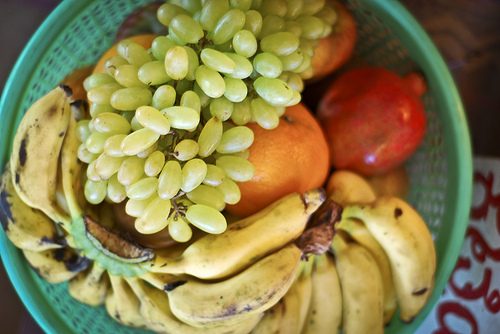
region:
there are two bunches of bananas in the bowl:
[20, 88, 452, 332]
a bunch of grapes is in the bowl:
[74, 5, 344, 237]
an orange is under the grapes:
[222, 98, 329, 214]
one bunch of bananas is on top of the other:
[13, 86, 415, 332]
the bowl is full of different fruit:
[0, 2, 472, 329]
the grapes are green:
[75, 2, 337, 232]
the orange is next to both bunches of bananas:
[235, 104, 331, 210]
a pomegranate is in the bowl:
[315, 63, 422, 167]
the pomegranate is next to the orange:
[231, 66, 427, 215]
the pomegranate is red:
[326, 56, 431, 168]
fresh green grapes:
[73, 0, 340, 255]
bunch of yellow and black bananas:
[3, 78, 453, 332]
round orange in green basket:
[217, 97, 337, 223]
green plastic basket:
[6, 0, 489, 328]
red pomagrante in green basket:
[317, 56, 428, 171]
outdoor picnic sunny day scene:
[10, 1, 496, 326]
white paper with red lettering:
[417, 155, 497, 326]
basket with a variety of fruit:
[5, 0, 490, 326]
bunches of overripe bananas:
[7, 77, 468, 329]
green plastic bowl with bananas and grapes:
[6, 1, 498, 328]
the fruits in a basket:
[24, 52, 411, 332]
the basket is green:
[19, 13, 481, 321]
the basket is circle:
[10, 14, 490, 314]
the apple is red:
[325, 62, 447, 212]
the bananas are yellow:
[185, 233, 458, 328]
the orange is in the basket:
[181, 69, 491, 305]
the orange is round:
[242, 80, 359, 247]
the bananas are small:
[119, 212, 293, 329]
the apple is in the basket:
[311, 35, 498, 282]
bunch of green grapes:
[104, 30, 267, 185]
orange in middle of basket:
[238, 91, 336, 214]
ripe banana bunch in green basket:
[243, 201, 430, 320]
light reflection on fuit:
[362, 114, 411, 166]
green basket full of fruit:
[7, 6, 467, 319]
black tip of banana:
[54, 75, 84, 102]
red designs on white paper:
[459, 193, 496, 314]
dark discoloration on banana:
[387, 199, 407, 224]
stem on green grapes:
[167, 195, 184, 220]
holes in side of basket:
[54, 17, 103, 69]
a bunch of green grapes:
[112, 76, 217, 223]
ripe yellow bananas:
[157, 241, 384, 321]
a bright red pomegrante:
[318, 51, 420, 174]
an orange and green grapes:
[220, 96, 341, 203]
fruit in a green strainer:
[14, 9, 479, 309]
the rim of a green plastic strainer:
[420, 81, 474, 263]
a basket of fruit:
[16, 28, 476, 330]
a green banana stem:
[37, 186, 199, 304]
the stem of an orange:
[271, 101, 311, 134]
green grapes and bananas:
[137, 195, 368, 297]